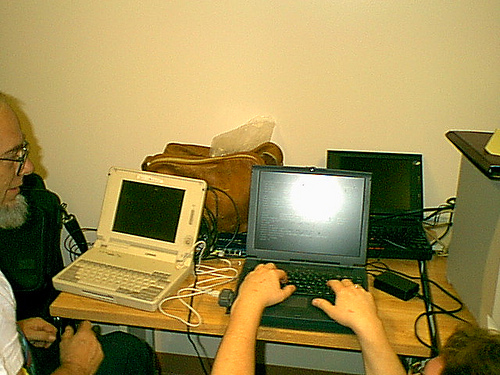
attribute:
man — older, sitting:
[0, 95, 160, 374]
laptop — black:
[236, 149, 408, 322]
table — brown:
[49, 182, 496, 358]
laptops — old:
[51, 147, 432, 330]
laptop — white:
[50, 162, 205, 305]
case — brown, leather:
[140, 130, 300, 236]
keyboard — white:
[71, 249, 196, 324]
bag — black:
[0, 187, 88, 322]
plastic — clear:
[208, 119, 275, 159]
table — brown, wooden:
[54, 244, 488, 370]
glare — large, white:
[290, 175, 343, 224]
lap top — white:
[47, 162, 220, 319]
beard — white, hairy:
[1, 193, 33, 232]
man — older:
[0, 94, 37, 234]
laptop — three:
[75, 163, 221, 325]